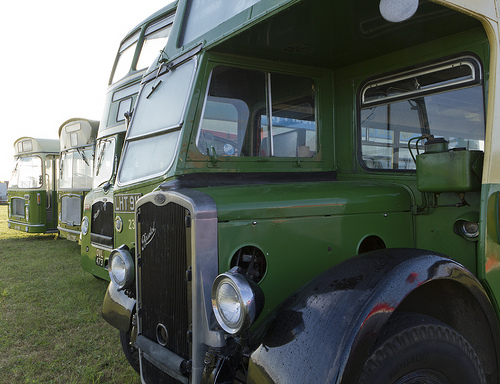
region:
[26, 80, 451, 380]
row of green buses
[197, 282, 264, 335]
small lights on bus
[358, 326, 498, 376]
black tires on bus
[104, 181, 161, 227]
license plate on bus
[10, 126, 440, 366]
buses are on grass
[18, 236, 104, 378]
green grass in shadow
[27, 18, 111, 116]
sky is bright grey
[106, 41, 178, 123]
second level to bus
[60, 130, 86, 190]
windshield wipers on buses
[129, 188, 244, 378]
black grill on bus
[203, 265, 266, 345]
Headlight on the right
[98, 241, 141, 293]
Headlight on the left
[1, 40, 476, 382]
Buses side by side each other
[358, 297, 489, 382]
Black rubber tire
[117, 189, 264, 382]
Front end of bus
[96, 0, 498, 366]
Truck is green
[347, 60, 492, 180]
Windshield of truck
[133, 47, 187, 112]
Windshield wiper on the front of truck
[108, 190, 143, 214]
Sign plaque on front of bus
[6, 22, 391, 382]
Trucks parked in the grass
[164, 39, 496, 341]
A big green bus head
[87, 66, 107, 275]
A big green bus head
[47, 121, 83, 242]
A big green bus head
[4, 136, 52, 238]
A big green bus head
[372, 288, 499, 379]
A big black bus wheel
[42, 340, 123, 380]
A Green grass surface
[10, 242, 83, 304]
A Green grass surface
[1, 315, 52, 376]
A Green grass surface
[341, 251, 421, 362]
fender is reflecting red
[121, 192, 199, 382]
front grill on an old bus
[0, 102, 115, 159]
destinations were once displayed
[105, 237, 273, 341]
headlights mounted on fenders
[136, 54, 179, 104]
a small windshield wiper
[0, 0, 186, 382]
buses parked on the grass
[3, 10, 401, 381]
buses are painted green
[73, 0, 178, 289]
a bus with a second tier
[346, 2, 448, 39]
mirror hangs from above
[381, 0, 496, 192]
upper section of this bus is a lighter green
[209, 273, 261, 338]
a bus front headlight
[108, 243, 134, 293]
a bus front headlight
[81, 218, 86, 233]
a bus front headlight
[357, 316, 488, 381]
a bus front left tire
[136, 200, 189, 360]
a black radiator grille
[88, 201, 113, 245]
a black radiator grille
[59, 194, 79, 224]
a chrome radiator grille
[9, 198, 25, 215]
a chrome radiator grille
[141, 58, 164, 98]
a bus' windshield wiper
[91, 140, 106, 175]
a bus' windshield wiper